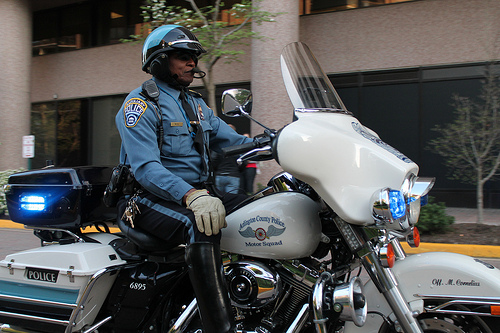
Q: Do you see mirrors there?
A: Yes, there is a mirror.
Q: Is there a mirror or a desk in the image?
A: Yes, there is a mirror.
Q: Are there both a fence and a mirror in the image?
A: No, there is a mirror but no fences.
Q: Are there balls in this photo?
A: No, there are no balls.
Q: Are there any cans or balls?
A: No, there are no balls or cans.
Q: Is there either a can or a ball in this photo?
A: No, there are no balls or cans.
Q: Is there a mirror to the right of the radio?
A: Yes, there is a mirror to the right of the radio.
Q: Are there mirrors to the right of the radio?
A: Yes, there is a mirror to the right of the radio.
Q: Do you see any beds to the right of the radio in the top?
A: No, there is a mirror to the right of the radio.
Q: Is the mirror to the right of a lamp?
A: No, the mirror is to the right of the radio.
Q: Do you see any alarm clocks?
A: No, there are no alarm clocks.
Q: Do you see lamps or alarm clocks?
A: No, there are no alarm clocks or lamps.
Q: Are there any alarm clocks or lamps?
A: No, there are no alarm clocks or lamps.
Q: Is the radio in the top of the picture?
A: Yes, the radio is in the top of the image.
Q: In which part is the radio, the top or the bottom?
A: The radio is in the top of the image.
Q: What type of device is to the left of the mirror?
A: The device is a radio.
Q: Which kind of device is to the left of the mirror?
A: The device is a radio.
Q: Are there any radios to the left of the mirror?
A: Yes, there is a radio to the left of the mirror.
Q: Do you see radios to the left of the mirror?
A: Yes, there is a radio to the left of the mirror.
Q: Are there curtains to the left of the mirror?
A: No, there is a radio to the left of the mirror.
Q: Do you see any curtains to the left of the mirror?
A: No, there is a radio to the left of the mirror.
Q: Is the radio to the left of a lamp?
A: No, the radio is to the left of the mirror.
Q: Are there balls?
A: No, there are no balls.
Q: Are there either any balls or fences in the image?
A: No, there are no balls or fences.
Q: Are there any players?
A: No, there are no players.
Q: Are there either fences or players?
A: No, there are no players or fences.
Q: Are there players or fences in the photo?
A: No, there are no players or fences.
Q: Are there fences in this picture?
A: No, there are no fences.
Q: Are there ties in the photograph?
A: Yes, there is a tie.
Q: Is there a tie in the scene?
A: Yes, there is a tie.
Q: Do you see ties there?
A: Yes, there is a tie.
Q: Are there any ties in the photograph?
A: Yes, there is a tie.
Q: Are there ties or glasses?
A: Yes, there is a tie.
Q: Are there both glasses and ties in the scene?
A: No, there is a tie but no glasses.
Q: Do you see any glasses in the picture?
A: No, there are no glasses.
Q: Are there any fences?
A: No, there are no fences.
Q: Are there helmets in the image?
A: Yes, there is a helmet.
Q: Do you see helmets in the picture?
A: Yes, there is a helmet.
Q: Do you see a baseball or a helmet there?
A: Yes, there is a helmet.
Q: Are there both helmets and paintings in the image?
A: No, there is a helmet but no paintings.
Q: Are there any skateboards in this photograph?
A: No, there are no skateboards.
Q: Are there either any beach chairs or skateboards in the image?
A: No, there are no skateboards or beach chairs.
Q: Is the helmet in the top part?
A: Yes, the helmet is in the top of the image.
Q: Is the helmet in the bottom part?
A: No, the helmet is in the top of the image.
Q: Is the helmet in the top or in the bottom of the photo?
A: The helmet is in the top of the image.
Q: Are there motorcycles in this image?
A: Yes, there is a motorcycle.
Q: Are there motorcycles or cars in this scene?
A: Yes, there is a motorcycle.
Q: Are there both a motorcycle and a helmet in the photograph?
A: Yes, there are both a motorcycle and a helmet.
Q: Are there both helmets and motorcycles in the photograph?
A: Yes, there are both a motorcycle and a helmet.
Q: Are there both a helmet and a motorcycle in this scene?
A: Yes, there are both a motorcycle and a helmet.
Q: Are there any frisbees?
A: No, there are no frisbees.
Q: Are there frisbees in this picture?
A: No, there are no frisbees.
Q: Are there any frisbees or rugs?
A: No, there are no frisbees or rugs.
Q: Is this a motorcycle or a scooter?
A: This is a motorcycle.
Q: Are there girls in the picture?
A: No, there are no girls.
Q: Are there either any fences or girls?
A: No, there are no girls or fences.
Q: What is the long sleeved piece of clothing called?
A: The clothing item is a shirt.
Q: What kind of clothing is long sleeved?
A: The clothing is a shirt.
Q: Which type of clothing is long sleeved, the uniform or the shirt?
A: The shirt is long sleeved.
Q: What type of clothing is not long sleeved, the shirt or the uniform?
A: The uniform is not long sleeved.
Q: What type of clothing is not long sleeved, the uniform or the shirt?
A: The uniform is not long sleeved.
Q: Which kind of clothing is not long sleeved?
A: The clothing is a uniform.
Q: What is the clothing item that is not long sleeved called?
A: The clothing item is a uniform.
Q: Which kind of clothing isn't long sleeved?
A: The clothing is a uniform.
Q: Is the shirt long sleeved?
A: Yes, the shirt is long sleeved.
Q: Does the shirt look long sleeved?
A: Yes, the shirt is long sleeved.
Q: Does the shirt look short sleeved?
A: No, the shirt is long sleeved.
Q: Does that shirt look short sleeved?
A: No, the shirt is long sleeved.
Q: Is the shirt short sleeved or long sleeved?
A: The shirt is long sleeved.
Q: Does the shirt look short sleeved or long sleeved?
A: The shirt is long sleeved.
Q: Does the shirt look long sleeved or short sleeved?
A: The shirt is long sleeved.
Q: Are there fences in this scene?
A: No, there are no fences.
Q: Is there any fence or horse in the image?
A: No, there are no fences or horses.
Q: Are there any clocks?
A: No, there are no clocks.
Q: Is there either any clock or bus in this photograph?
A: No, there are no clocks or buses.